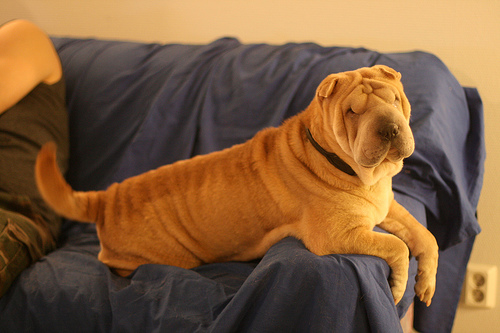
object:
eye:
[341, 103, 358, 120]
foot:
[413, 270, 438, 306]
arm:
[1, 17, 46, 114]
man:
[0, 16, 68, 293]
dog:
[32, 65, 440, 307]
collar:
[300, 123, 355, 176]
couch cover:
[2, 35, 485, 333]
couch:
[0, 35, 485, 333]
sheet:
[0, 36, 488, 333]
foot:
[391, 283, 405, 307]